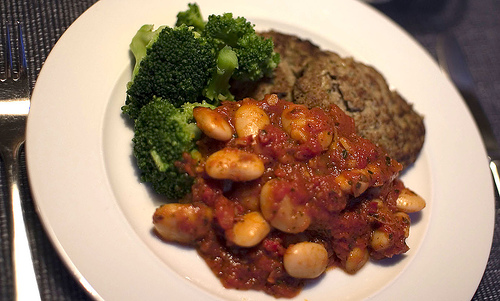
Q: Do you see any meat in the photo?
A: Yes, there is meat.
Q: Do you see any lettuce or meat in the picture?
A: Yes, there is meat.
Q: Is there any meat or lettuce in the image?
A: Yes, there is meat.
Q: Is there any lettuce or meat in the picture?
A: Yes, there is meat.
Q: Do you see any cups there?
A: No, there are no cups.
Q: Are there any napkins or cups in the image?
A: No, there are no cups or napkins.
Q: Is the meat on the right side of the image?
A: Yes, the meat is on the right of the image.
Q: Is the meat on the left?
A: No, the meat is on the right of the image.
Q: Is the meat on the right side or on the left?
A: The meat is on the right of the image.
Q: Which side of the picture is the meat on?
A: The meat is on the right of the image.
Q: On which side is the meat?
A: The meat is on the right of the image.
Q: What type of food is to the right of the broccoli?
A: The food is meat.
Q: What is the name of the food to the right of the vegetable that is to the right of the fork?
A: The food is meat.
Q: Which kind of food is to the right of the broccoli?
A: The food is meat.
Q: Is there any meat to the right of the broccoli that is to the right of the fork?
A: Yes, there is meat to the right of the broccoli.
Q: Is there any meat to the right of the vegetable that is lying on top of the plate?
A: Yes, there is meat to the right of the broccoli.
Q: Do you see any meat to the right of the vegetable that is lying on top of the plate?
A: Yes, there is meat to the right of the broccoli.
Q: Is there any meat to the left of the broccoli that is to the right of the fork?
A: No, the meat is to the right of the broccoli.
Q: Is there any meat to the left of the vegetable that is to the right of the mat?
A: No, the meat is to the right of the broccoli.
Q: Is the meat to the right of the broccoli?
A: Yes, the meat is to the right of the broccoli.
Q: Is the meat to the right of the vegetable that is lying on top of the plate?
A: Yes, the meat is to the right of the broccoli.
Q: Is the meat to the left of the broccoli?
A: No, the meat is to the right of the broccoli.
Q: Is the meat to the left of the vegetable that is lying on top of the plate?
A: No, the meat is to the right of the broccoli.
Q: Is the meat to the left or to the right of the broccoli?
A: The meat is to the right of the broccoli.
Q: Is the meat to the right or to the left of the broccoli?
A: The meat is to the right of the broccoli.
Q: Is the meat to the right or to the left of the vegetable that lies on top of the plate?
A: The meat is to the right of the broccoli.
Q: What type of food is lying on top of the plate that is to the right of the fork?
A: The food is meat.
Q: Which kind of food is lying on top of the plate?
A: The food is meat.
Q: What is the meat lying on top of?
A: The meat is lying on top of the plate.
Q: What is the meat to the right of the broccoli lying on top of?
A: The meat is lying on top of the plate.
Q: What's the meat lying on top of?
A: The meat is lying on top of the plate.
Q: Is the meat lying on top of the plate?
A: Yes, the meat is lying on top of the plate.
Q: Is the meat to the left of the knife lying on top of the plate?
A: Yes, the meat is lying on top of the plate.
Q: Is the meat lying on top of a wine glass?
A: No, the meat is lying on top of the plate.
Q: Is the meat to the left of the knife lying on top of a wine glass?
A: No, the meat is lying on top of the plate.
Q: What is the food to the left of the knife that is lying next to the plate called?
A: The food is meat.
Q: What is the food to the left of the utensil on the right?
A: The food is meat.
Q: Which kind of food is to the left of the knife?
A: The food is meat.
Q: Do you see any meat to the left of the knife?
A: Yes, there is meat to the left of the knife.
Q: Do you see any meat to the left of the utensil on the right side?
A: Yes, there is meat to the left of the knife.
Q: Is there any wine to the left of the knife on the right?
A: No, there is meat to the left of the knife.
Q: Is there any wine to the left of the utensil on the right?
A: No, there is meat to the left of the knife.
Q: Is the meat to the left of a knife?
A: Yes, the meat is to the left of a knife.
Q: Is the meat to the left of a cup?
A: No, the meat is to the left of a knife.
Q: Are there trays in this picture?
A: No, there are no trays.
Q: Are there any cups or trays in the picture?
A: No, there are no trays or cups.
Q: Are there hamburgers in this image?
A: Yes, there are hamburgers.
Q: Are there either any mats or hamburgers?
A: Yes, there are hamburgers.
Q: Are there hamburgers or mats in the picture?
A: Yes, there are hamburgers.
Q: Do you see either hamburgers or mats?
A: Yes, there are hamburgers.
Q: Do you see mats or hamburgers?
A: Yes, there are hamburgers.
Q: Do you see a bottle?
A: No, there are no bottles.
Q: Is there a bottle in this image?
A: No, there are no bottles.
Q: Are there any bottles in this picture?
A: No, there are no bottles.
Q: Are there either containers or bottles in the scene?
A: No, there are no bottles or containers.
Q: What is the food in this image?
A: The food is hamburgers.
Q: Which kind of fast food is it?
A: The food is hamburgers.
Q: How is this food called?
A: These are hamburgers.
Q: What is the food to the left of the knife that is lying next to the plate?
A: The food is hamburgers.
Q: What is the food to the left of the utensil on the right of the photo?
A: The food is hamburgers.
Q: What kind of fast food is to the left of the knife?
A: The food is hamburgers.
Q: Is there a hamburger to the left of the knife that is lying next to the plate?
A: Yes, there are hamburgers to the left of the knife.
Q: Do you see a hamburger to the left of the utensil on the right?
A: Yes, there are hamburgers to the left of the knife.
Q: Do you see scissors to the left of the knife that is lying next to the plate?
A: No, there are hamburgers to the left of the knife.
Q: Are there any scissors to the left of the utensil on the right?
A: No, there are hamburgers to the left of the knife.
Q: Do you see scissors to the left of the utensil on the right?
A: No, there are hamburgers to the left of the knife.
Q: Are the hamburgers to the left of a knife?
A: Yes, the hamburgers are to the left of a knife.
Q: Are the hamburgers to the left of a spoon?
A: No, the hamburgers are to the left of a knife.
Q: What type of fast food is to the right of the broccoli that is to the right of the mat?
A: The food is hamburgers.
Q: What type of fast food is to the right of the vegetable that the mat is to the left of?
A: The food is hamburgers.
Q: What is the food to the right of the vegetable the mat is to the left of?
A: The food is hamburgers.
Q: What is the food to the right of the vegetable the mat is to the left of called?
A: The food is hamburgers.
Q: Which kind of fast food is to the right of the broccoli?
A: The food is hamburgers.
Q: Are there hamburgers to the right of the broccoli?
A: Yes, there are hamburgers to the right of the broccoli.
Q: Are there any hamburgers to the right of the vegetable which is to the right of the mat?
A: Yes, there are hamburgers to the right of the broccoli.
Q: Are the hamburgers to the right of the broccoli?
A: Yes, the hamburgers are to the right of the broccoli.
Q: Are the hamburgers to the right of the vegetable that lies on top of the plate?
A: Yes, the hamburgers are to the right of the broccoli.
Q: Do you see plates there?
A: Yes, there is a plate.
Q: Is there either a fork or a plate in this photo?
A: Yes, there is a plate.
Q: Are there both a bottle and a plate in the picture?
A: No, there is a plate but no bottles.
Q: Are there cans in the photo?
A: No, there are no cans.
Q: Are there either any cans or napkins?
A: No, there are no cans or napkins.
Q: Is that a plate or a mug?
A: That is a plate.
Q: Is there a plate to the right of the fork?
A: Yes, there is a plate to the right of the fork.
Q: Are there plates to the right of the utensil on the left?
A: Yes, there is a plate to the right of the fork.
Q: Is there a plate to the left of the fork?
A: No, the plate is to the right of the fork.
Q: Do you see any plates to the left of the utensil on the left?
A: No, the plate is to the right of the fork.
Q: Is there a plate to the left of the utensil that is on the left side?
A: No, the plate is to the right of the fork.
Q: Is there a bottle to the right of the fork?
A: No, there is a plate to the right of the fork.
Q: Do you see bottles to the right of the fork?
A: No, there is a plate to the right of the fork.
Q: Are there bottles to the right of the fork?
A: No, there is a plate to the right of the fork.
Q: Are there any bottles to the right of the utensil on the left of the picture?
A: No, there is a plate to the right of the fork.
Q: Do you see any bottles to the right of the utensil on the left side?
A: No, there is a plate to the right of the fork.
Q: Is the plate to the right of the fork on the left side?
A: Yes, the plate is to the right of the fork.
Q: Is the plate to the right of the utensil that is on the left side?
A: Yes, the plate is to the right of the fork.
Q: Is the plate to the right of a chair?
A: No, the plate is to the right of the fork.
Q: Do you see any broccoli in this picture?
A: Yes, there is broccoli.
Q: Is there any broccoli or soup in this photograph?
A: Yes, there is broccoli.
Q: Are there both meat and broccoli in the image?
A: Yes, there are both broccoli and meat.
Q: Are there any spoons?
A: No, there are no spoons.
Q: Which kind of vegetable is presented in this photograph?
A: The vegetable is broccoli.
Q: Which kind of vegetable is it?
A: The vegetable is broccoli.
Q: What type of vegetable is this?
A: This is broccoli.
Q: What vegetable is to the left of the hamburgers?
A: The vegetable is broccoli.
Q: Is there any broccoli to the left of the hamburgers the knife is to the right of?
A: Yes, there is broccoli to the left of the hamburgers.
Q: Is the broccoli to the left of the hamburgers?
A: Yes, the broccoli is to the left of the hamburgers.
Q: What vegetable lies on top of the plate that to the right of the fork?
A: The vegetable is broccoli.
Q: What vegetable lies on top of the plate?
A: The vegetable is broccoli.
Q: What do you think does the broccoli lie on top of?
A: The broccoli lies on top of the plate.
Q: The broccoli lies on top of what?
A: The broccoli lies on top of the plate.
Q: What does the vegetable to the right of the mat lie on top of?
A: The broccoli lies on top of the plate.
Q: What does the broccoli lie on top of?
A: The broccoli lies on top of the plate.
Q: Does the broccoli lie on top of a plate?
A: Yes, the broccoli lies on top of a plate.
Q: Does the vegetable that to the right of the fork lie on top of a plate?
A: Yes, the broccoli lies on top of a plate.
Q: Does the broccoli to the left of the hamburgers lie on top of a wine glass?
A: No, the broccoli lies on top of a plate.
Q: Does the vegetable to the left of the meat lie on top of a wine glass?
A: No, the broccoli lies on top of a plate.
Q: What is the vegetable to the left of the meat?
A: The vegetable is broccoli.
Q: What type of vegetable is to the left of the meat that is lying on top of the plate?
A: The vegetable is broccoli.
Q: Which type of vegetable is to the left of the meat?
A: The vegetable is broccoli.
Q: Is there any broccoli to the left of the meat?
A: Yes, there is broccoli to the left of the meat.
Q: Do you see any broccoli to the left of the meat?
A: Yes, there is broccoli to the left of the meat.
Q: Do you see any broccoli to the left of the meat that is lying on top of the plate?
A: Yes, there is broccoli to the left of the meat.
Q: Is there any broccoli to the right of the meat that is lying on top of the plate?
A: No, the broccoli is to the left of the meat.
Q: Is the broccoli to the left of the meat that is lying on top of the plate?
A: Yes, the broccoli is to the left of the meat.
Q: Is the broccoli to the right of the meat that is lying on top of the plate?
A: No, the broccoli is to the left of the meat.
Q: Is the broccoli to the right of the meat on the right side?
A: No, the broccoli is to the left of the meat.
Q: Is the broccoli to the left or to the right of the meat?
A: The broccoli is to the left of the meat.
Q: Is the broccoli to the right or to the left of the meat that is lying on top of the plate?
A: The broccoli is to the left of the meat.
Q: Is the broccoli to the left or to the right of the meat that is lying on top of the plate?
A: The broccoli is to the left of the meat.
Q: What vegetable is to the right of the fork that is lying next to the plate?
A: The vegetable is broccoli.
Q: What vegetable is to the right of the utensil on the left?
A: The vegetable is broccoli.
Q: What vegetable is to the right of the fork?
A: The vegetable is broccoli.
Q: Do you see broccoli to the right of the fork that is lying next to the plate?
A: Yes, there is broccoli to the right of the fork.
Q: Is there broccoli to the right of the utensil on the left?
A: Yes, there is broccoli to the right of the fork.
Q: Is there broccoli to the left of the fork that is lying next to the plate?
A: No, the broccoli is to the right of the fork.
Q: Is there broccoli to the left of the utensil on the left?
A: No, the broccoli is to the right of the fork.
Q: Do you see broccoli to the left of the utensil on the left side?
A: No, the broccoli is to the right of the fork.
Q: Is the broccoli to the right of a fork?
A: Yes, the broccoli is to the right of a fork.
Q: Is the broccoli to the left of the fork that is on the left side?
A: No, the broccoli is to the right of the fork.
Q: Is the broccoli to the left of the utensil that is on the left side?
A: No, the broccoli is to the right of the fork.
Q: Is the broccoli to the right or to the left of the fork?
A: The broccoli is to the right of the fork.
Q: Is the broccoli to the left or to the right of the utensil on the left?
A: The broccoli is to the right of the fork.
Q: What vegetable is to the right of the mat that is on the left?
A: The vegetable is broccoli.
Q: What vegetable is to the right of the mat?
A: The vegetable is broccoli.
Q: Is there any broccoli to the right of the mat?
A: Yes, there is broccoli to the right of the mat.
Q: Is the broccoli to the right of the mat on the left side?
A: Yes, the broccoli is to the right of the mat.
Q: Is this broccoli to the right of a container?
A: No, the broccoli is to the right of the mat.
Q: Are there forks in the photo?
A: Yes, there is a fork.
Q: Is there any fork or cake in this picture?
A: Yes, there is a fork.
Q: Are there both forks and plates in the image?
A: Yes, there are both a fork and a plate.